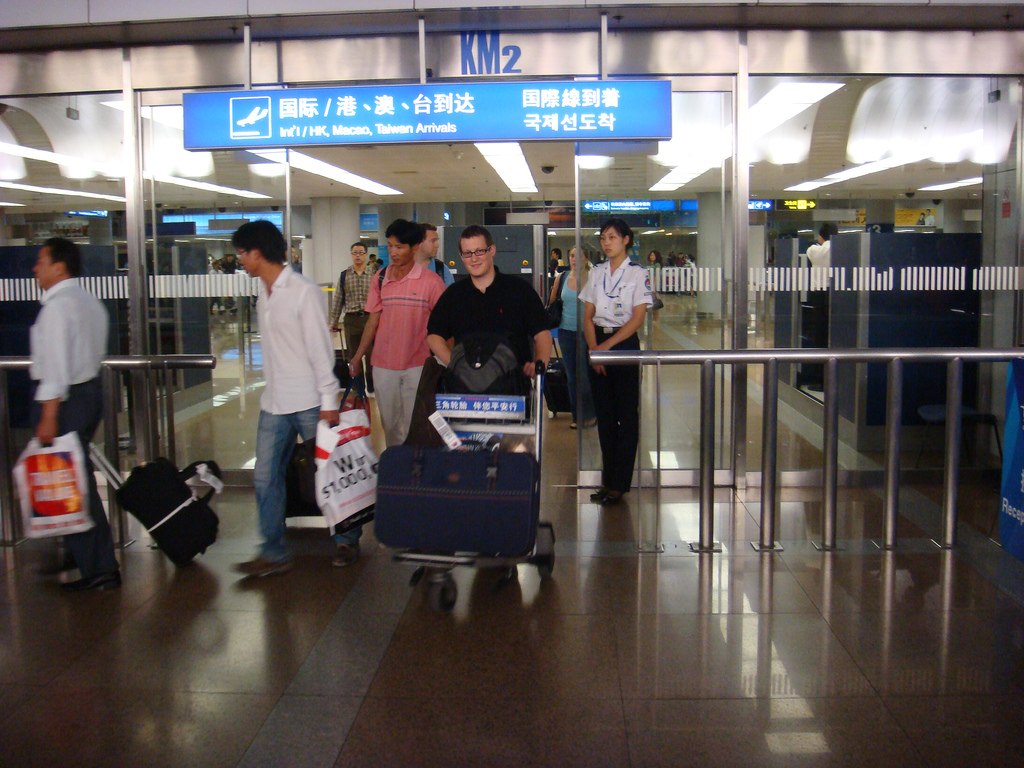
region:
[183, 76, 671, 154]
a blue sign has white characters and lettering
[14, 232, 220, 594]
a man is walking pulling a wheeled luggage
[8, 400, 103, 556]
a man is holding a plastic bag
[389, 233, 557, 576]
a man is pushing a luggage cart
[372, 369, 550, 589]
black luggage is on the cart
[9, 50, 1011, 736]
an exit door from the airport luggage area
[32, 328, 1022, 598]
a stainless steel fence is by the doors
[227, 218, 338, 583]
Asian male airport deboarding passenger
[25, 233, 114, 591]
Asian male airport deboarding passenger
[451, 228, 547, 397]
Caucasian male with eye glasses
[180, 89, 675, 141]
Asian blue and white airport sign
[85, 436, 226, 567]
black wheeled luggage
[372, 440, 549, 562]
black luggage bag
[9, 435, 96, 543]
white and red shopping bag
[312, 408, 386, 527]
white and red shopping bag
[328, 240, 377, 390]
male deboarding airplane passenger with luggage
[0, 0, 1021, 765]
The arrivals unit in an airport.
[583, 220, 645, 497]
The female airport personnel at the exit.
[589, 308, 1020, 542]
Metal restraints at the entrance.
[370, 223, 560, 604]
The traveler with a blue luggage cart.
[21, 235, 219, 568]
The traveler pulling a wheeled suitcase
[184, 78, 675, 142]
The airport arrivals scheduler in foreign language.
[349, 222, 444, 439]
The person in a pink shirt.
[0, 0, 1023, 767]
The airport arrivals exit.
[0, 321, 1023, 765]
The smooth tile finished floor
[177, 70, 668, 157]
light blue sign with white writing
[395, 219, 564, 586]
man pushing luggage cart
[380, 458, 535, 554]
navy blue suitcase on the luggage cart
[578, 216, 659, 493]
woman wearing navy pants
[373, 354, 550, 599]
luggage cart man is pushing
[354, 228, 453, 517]
man wearing pink shirt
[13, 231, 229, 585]
man pulling black luggage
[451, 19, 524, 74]
blue lettering on silver background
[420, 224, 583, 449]
man wearing eyeglasses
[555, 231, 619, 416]
woman wearing blue shirt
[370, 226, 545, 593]
Man in black shirt pushing luggage cart.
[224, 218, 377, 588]
Man wearing white shirt and carrying shopping bag.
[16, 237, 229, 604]
Man toting plastic bag and pulling black luggage.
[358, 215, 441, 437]
Person wearing pink shirt and white pants.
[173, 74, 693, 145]
Large blue and white sign.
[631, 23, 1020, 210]
Long bright ceiling lights.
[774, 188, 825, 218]
A small black and yellow sign.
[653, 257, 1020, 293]
White markings on the glass.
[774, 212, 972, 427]
Man standing in a gray cubicle.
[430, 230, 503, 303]
the head of a man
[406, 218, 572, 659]
a person in the airport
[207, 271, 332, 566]
a person in the airport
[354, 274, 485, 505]
a person in the airport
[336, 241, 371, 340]
a person in the airport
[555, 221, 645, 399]
a person in the airport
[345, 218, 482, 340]
a person in the airport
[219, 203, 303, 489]
a person in the airport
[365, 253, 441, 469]
a person in the airport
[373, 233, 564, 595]
man pushing a luggage cart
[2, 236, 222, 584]
man pulling his luggage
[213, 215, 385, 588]
man carrying a white bag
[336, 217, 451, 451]
person in a pink shirt